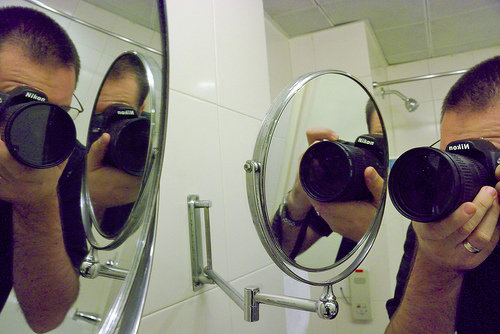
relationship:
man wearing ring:
[368, 47, 497, 332] [453, 236, 483, 261]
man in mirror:
[19, 41, 199, 253] [271, 73, 429, 303]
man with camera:
[0, 5, 105, 332] [0, 71, 84, 183]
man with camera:
[368, 47, 497, 332] [387, 137, 477, 240]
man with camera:
[368, 47, 497, 332] [387, 132, 495, 227]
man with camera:
[0, 5, 90, 334] [1, 87, 78, 170]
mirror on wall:
[0, 3, 174, 332] [172, 1, 493, 332]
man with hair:
[368, 47, 497, 332] [420, 63, 492, 134]